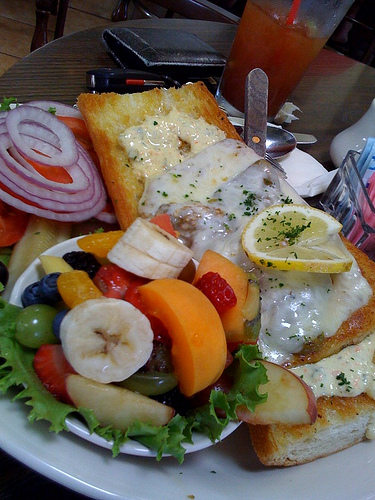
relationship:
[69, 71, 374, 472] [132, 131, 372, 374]
fish covered in sauce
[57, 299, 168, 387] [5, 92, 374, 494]
banana slice on plate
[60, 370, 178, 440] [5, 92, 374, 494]
slice of fruit on plate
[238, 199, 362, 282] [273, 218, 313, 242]
lemon wedge has parsley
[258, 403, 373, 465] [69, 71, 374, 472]
cut edge of fish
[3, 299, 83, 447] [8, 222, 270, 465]
lettuce in bowl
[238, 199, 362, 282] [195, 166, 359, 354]
lemon wedge on top of cheese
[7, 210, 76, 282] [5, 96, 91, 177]
pickle spear by onion slice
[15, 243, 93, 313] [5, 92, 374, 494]
blueberries are on plate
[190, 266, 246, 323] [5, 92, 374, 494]
berry on plate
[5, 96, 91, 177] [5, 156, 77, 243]
onion slice on top of tomato slice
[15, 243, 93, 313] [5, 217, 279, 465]
blueberries are in fruit salad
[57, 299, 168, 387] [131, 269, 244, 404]
banana slice by orange slice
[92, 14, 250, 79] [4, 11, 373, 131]
wallet on table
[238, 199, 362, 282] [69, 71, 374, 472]
lemon wedge on fish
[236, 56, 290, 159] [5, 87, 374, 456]
wooden utensil under food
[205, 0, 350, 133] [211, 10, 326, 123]
glass contains orange drink